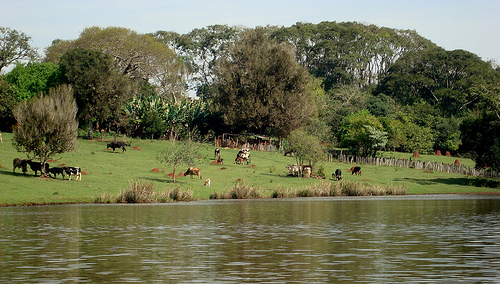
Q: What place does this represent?
A: It represents the pond.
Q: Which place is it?
A: It is a pond.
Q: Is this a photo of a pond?
A: Yes, it is showing a pond.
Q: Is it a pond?
A: Yes, it is a pond.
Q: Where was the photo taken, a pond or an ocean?
A: It was taken at a pond.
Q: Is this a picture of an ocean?
A: No, the picture is showing a pond.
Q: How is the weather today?
A: It is clear.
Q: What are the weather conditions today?
A: It is clear.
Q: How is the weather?
A: It is clear.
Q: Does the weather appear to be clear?
A: Yes, it is clear.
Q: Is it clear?
A: Yes, it is clear.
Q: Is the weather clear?
A: Yes, it is clear.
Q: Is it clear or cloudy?
A: It is clear.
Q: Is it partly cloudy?
A: No, it is clear.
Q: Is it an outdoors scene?
A: Yes, it is outdoors.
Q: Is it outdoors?
A: Yes, it is outdoors.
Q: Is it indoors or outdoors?
A: It is outdoors.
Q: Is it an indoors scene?
A: No, it is outdoors.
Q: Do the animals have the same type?
A: Yes, all the animals are cows.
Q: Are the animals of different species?
A: No, all the animals are cows.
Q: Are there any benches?
A: No, there are no benches.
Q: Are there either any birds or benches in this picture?
A: No, there are no benches or birds.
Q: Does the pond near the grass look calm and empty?
A: Yes, the pond is calm and empty.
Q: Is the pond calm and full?
A: No, the pond is calm but empty.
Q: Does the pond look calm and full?
A: No, the pond is calm but empty.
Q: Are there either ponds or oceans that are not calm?
A: No, there is a pond but it is calm.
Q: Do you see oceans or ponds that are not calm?
A: No, there is a pond but it is calm.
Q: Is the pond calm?
A: Yes, the pond is calm.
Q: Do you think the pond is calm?
A: Yes, the pond is calm.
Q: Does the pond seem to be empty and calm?
A: Yes, the pond is empty and calm.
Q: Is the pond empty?
A: Yes, the pond is empty.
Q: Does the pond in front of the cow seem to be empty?
A: Yes, the pond is empty.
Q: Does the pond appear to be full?
A: No, the pond is empty.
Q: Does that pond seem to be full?
A: No, the pond is empty.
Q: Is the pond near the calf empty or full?
A: The pond is empty.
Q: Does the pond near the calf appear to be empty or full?
A: The pond is empty.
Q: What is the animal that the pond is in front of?
A: The animal is a cow.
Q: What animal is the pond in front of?
A: The pond is in front of the cow.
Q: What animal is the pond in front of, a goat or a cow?
A: The pond is in front of a cow.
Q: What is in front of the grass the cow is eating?
A: The pond is in front of the grass.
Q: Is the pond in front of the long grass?
A: Yes, the pond is in front of the grass.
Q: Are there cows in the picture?
A: Yes, there is a cow.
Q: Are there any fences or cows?
A: Yes, there is a cow.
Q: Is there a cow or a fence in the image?
A: Yes, there is a cow.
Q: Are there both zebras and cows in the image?
A: No, there is a cow but no zebras.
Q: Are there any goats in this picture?
A: No, there are no goats.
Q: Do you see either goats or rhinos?
A: No, there are no goats or rhinos.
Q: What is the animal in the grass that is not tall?
A: The animal is a cow.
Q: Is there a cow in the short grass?
A: Yes, there is a cow in the grass.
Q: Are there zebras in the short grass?
A: No, there is a cow in the grass.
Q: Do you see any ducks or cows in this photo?
A: Yes, there is a cow.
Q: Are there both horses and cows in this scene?
A: No, there is a cow but no horses.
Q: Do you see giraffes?
A: No, there are no giraffes.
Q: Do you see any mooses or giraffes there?
A: No, there are no giraffes or mooses.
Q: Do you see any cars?
A: No, there are no cars.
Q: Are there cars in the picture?
A: No, there are no cars.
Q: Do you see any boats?
A: No, there are no boats.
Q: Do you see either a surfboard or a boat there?
A: No, there are no boats or surfboards.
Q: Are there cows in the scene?
A: Yes, there is a cow.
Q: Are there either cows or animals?
A: Yes, there is a cow.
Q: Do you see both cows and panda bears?
A: No, there is a cow but no pandas.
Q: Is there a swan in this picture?
A: No, there are no swans.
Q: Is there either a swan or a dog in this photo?
A: No, there are no swans or dogs.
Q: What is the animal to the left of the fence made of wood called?
A: The animal is a cow.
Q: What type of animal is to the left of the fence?
A: The animal is a cow.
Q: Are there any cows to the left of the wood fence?
A: Yes, there is a cow to the left of the fence.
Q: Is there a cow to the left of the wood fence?
A: Yes, there is a cow to the left of the fence.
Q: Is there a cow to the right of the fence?
A: No, the cow is to the left of the fence.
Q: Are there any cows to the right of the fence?
A: No, the cow is to the left of the fence.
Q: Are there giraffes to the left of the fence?
A: No, there is a cow to the left of the fence.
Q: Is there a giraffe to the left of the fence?
A: No, there is a cow to the left of the fence.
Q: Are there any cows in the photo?
A: Yes, there is a cow.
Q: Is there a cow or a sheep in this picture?
A: Yes, there is a cow.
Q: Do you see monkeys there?
A: No, there are no monkeys.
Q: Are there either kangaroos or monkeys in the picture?
A: No, there are no monkeys or kangaroos.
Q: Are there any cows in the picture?
A: Yes, there is a cow.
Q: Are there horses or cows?
A: Yes, there is a cow.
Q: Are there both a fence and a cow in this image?
A: Yes, there are both a cow and a fence.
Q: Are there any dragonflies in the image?
A: No, there are no dragonflies.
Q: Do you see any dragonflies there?
A: No, there are no dragonflies.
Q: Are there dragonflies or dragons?
A: No, there are no dragonflies or dragons.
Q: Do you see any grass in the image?
A: Yes, there is grass.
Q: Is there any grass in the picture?
A: Yes, there is grass.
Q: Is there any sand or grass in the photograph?
A: Yes, there is grass.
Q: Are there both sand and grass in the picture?
A: No, there is grass but no sand.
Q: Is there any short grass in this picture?
A: Yes, there is short grass.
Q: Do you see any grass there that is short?
A: Yes, there is grass that is short.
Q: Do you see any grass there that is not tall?
A: Yes, there is short grass.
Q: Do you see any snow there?
A: No, there is no snow.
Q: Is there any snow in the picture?
A: No, there is no snow.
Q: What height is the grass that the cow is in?
A: The grass is short.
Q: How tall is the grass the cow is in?
A: The grass is short.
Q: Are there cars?
A: No, there are no cars.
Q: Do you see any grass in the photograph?
A: Yes, there is grass.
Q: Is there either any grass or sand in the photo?
A: Yes, there is grass.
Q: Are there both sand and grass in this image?
A: No, there is grass but no sand.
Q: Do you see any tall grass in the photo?
A: Yes, there is tall grass.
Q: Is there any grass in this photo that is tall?
A: Yes, there is grass that is tall.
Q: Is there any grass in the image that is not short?
A: Yes, there is tall grass.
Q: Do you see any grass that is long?
A: Yes, there is long grass.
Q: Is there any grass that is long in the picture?
A: Yes, there is long grass.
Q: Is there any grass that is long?
A: Yes, there is grass that is long.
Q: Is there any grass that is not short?
A: Yes, there is long grass.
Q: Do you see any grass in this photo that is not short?
A: Yes, there is long grass.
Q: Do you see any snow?
A: No, there is no snow.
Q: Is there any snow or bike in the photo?
A: No, there are no snow or bikes.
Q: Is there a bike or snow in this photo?
A: No, there are no snow or bikes.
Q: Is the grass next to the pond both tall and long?
A: Yes, the grass is tall and long.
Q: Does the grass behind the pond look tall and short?
A: No, the grass is tall but long.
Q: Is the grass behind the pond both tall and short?
A: No, the grass is tall but long.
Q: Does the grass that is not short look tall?
A: Yes, the grass is tall.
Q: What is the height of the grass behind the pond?
A: The grass is tall.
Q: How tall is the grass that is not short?
A: The grass is tall.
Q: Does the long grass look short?
A: No, the grass is tall.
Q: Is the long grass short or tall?
A: The grass is tall.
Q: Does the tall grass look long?
A: Yes, the grass is long.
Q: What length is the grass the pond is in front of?
A: The grass is long.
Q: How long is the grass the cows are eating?
A: The grass is long.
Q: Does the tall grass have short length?
A: No, the grass is long.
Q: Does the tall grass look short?
A: No, the grass is long.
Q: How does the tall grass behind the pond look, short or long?
A: The grass is long.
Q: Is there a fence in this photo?
A: Yes, there is a fence.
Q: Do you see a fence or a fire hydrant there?
A: Yes, there is a fence.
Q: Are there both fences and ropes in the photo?
A: No, there is a fence but no ropes.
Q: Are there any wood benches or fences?
A: Yes, there is a wood fence.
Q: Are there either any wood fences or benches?
A: Yes, there is a wood fence.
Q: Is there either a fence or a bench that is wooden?
A: Yes, the fence is wooden.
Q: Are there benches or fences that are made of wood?
A: Yes, the fence is made of wood.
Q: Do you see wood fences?
A: Yes, there is a fence that is made of wood.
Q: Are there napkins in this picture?
A: No, there are no napkins.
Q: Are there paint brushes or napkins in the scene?
A: No, there are no napkins or paint brushes.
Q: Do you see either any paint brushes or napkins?
A: No, there are no napkins or paint brushes.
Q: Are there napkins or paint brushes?
A: No, there are no napkins or paint brushes.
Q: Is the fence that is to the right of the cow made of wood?
A: Yes, the fence is made of wood.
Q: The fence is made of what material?
A: The fence is made of wood.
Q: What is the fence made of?
A: The fence is made of wood.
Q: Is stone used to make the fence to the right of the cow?
A: No, the fence is made of wood.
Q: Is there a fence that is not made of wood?
A: No, there is a fence but it is made of wood.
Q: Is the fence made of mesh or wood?
A: The fence is made of wood.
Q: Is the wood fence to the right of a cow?
A: Yes, the fence is to the right of a cow.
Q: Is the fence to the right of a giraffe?
A: No, the fence is to the right of a cow.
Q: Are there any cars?
A: No, there are no cars.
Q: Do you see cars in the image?
A: No, there are no cars.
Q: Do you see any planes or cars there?
A: No, there are no cars or planes.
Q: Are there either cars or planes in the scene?
A: No, there are no cars or planes.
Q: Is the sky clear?
A: Yes, the sky is clear.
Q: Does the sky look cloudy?
A: No, the sky is clear.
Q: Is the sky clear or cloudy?
A: The sky is clear.